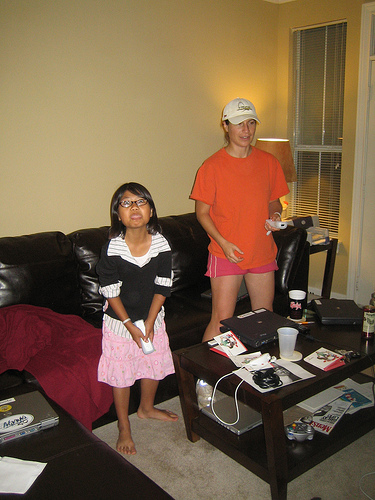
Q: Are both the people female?
A: Yes, all the people are female.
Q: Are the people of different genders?
A: No, all the people are female.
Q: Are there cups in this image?
A: Yes, there is a cup.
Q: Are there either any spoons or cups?
A: Yes, there is a cup.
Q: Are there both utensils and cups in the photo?
A: No, there is a cup but no utensils.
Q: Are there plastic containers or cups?
A: Yes, there is a plastic cup.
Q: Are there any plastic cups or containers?
A: Yes, there is a plastic cup.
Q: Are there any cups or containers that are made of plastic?
A: Yes, the cup is made of plastic.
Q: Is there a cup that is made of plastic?
A: Yes, there is a cup that is made of plastic.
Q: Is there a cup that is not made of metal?
A: Yes, there is a cup that is made of plastic.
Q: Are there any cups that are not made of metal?
A: Yes, there is a cup that is made of plastic.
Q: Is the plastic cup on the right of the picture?
A: Yes, the cup is on the right of the image.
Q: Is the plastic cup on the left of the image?
A: No, the cup is on the right of the image.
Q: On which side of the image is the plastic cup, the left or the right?
A: The cup is on the right of the image.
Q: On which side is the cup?
A: The cup is on the right of the image.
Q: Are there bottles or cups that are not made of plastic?
A: No, there is a cup but it is made of plastic.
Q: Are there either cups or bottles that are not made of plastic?
A: No, there is a cup but it is made of plastic.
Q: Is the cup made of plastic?
A: Yes, the cup is made of plastic.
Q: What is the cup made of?
A: The cup is made of plastic.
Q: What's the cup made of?
A: The cup is made of plastic.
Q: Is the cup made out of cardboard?
A: No, the cup is made of plastic.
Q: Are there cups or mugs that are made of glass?
A: No, there is a cup but it is made of plastic.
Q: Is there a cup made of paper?
A: No, there is a cup but it is made of plastic.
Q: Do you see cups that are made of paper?
A: No, there is a cup but it is made of plastic.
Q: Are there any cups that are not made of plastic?
A: No, there is a cup but it is made of plastic.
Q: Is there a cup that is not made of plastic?
A: No, there is a cup but it is made of plastic.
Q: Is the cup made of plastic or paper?
A: The cup is made of plastic.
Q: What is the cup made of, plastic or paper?
A: The cup is made of plastic.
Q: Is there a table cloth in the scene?
A: No, there are no tablecloths.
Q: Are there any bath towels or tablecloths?
A: No, there are no tablecloths or bath towels.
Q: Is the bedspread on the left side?
A: Yes, the bedspread is on the left of the image.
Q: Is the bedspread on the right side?
A: No, the bedspread is on the left of the image.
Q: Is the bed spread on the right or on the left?
A: The bed spread is on the left of the image.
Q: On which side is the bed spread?
A: The bed spread is on the left of the image.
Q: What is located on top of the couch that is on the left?
A: The bedspread is on top of the couch.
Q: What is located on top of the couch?
A: The bedspread is on top of the couch.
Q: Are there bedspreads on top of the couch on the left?
A: Yes, there is a bedspread on top of the couch.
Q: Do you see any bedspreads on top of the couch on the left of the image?
A: Yes, there is a bedspread on top of the couch.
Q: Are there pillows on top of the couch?
A: No, there is a bedspread on top of the couch.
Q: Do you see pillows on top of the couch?
A: No, there is a bedspread on top of the couch.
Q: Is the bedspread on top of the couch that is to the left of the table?
A: Yes, the bedspread is on top of the couch.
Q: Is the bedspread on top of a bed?
A: No, the bedspread is on top of the couch.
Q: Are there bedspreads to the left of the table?
A: Yes, there is a bedspread to the left of the table.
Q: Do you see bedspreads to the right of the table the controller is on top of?
A: No, the bedspread is to the left of the table.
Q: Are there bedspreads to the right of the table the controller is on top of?
A: No, the bedspread is to the left of the table.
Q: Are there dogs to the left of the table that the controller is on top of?
A: No, there is a bedspread to the left of the table.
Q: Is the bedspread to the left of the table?
A: Yes, the bedspread is to the left of the table.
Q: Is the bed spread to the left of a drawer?
A: No, the bed spread is to the left of the table.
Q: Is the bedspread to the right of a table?
A: No, the bedspread is to the left of a table.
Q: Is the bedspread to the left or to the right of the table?
A: The bedspread is to the left of the table.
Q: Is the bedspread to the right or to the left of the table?
A: The bedspread is to the left of the table.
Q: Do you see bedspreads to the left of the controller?
A: Yes, there is a bedspread to the left of the controller.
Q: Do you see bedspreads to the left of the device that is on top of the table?
A: Yes, there is a bedspread to the left of the controller.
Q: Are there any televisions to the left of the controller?
A: No, there is a bedspread to the left of the controller.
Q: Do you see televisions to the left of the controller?
A: No, there is a bedspread to the left of the controller.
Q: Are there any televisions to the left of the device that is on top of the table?
A: No, there is a bedspread to the left of the controller.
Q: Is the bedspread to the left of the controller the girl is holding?
A: Yes, the bedspread is to the left of the controller.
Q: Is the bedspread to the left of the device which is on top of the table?
A: Yes, the bedspread is to the left of the controller.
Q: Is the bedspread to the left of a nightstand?
A: No, the bedspread is to the left of the controller.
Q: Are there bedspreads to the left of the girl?
A: Yes, there is a bedspread to the left of the girl.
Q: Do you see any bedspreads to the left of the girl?
A: Yes, there is a bedspread to the left of the girl.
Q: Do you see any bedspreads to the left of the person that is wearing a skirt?
A: Yes, there is a bedspread to the left of the girl.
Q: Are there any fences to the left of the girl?
A: No, there is a bedspread to the left of the girl.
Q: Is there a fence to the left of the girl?
A: No, there is a bedspread to the left of the girl.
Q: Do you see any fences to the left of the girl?
A: No, there is a bedspread to the left of the girl.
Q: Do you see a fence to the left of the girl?
A: No, there is a bedspread to the left of the girl.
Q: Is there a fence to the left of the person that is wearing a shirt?
A: No, there is a bedspread to the left of the girl.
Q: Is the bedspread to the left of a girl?
A: Yes, the bedspread is to the left of a girl.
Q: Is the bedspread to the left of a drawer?
A: No, the bedspread is to the left of a girl.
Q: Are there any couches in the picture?
A: Yes, there is a couch.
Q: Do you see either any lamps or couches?
A: Yes, there is a couch.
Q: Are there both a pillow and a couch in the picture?
A: No, there is a couch but no pillows.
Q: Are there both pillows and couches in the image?
A: No, there is a couch but no pillows.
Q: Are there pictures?
A: No, there are no pictures.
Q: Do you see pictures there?
A: No, there are no pictures.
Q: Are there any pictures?
A: No, there are no pictures.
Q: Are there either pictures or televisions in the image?
A: No, there are no pictures or televisions.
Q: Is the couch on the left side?
A: Yes, the couch is on the left of the image.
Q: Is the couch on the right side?
A: No, the couch is on the left of the image.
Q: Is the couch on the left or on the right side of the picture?
A: The couch is on the left of the image.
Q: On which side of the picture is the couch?
A: The couch is on the left of the image.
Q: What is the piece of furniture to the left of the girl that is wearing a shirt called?
A: The piece of furniture is a couch.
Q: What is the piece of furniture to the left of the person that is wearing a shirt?
A: The piece of furniture is a couch.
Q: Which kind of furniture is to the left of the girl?
A: The piece of furniture is a couch.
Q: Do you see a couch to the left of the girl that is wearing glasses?
A: Yes, there is a couch to the left of the girl.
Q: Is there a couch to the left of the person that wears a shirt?
A: Yes, there is a couch to the left of the girl.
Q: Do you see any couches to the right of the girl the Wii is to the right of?
A: No, the couch is to the left of the girl.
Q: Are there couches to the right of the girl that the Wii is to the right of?
A: No, the couch is to the left of the girl.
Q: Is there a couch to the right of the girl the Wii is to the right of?
A: No, the couch is to the left of the girl.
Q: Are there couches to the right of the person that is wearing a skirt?
A: No, the couch is to the left of the girl.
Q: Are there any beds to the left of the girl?
A: No, there is a couch to the left of the girl.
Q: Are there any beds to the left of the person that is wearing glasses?
A: No, there is a couch to the left of the girl.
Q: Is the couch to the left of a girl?
A: Yes, the couch is to the left of a girl.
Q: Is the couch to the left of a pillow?
A: No, the couch is to the left of a girl.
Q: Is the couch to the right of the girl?
A: No, the couch is to the left of the girl.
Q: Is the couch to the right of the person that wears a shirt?
A: No, the couch is to the left of the girl.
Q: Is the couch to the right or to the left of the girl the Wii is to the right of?
A: The couch is to the left of the girl.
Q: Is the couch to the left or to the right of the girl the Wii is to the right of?
A: The couch is to the left of the girl.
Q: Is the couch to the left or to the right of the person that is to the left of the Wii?
A: The couch is to the left of the girl.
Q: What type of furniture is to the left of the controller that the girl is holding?
A: The piece of furniture is a couch.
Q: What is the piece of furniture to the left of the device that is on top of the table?
A: The piece of furniture is a couch.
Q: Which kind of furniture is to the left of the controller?
A: The piece of furniture is a couch.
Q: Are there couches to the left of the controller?
A: Yes, there is a couch to the left of the controller.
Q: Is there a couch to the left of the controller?
A: Yes, there is a couch to the left of the controller.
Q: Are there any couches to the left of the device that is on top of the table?
A: Yes, there is a couch to the left of the controller.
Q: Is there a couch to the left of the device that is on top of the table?
A: Yes, there is a couch to the left of the controller.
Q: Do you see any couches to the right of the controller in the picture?
A: No, the couch is to the left of the controller.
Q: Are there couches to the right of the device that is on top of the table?
A: No, the couch is to the left of the controller.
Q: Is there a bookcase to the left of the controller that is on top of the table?
A: No, there is a couch to the left of the controller.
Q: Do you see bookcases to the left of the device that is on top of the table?
A: No, there is a couch to the left of the controller.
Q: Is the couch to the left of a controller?
A: Yes, the couch is to the left of a controller.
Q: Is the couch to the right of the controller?
A: No, the couch is to the left of the controller.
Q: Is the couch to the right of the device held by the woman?
A: No, the couch is to the left of the controller.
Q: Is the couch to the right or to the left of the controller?
A: The couch is to the left of the controller.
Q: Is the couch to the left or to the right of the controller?
A: The couch is to the left of the controller.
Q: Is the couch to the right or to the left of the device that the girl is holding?
A: The couch is to the left of the controller.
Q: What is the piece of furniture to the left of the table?
A: The piece of furniture is a couch.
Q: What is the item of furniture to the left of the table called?
A: The piece of furniture is a couch.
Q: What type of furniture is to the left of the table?
A: The piece of furniture is a couch.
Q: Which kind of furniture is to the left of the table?
A: The piece of furniture is a couch.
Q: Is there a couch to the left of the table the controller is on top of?
A: Yes, there is a couch to the left of the table.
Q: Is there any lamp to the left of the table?
A: No, there is a couch to the left of the table.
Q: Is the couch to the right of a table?
A: No, the couch is to the left of a table.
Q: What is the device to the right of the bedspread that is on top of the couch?
A: The device is a controller.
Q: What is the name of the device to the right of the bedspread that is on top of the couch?
A: The device is a controller.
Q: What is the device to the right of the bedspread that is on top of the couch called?
A: The device is a controller.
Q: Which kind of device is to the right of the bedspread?
A: The device is a controller.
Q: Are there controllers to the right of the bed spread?
A: Yes, there is a controller to the right of the bed spread.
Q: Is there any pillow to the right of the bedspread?
A: No, there is a controller to the right of the bedspread.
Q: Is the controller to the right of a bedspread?
A: Yes, the controller is to the right of a bedspread.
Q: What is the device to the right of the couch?
A: The device is a controller.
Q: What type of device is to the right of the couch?
A: The device is a controller.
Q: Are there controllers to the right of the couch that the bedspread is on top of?
A: Yes, there is a controller to the right of the couch.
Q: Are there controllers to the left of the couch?
A: No, the controller is to the right of the couch.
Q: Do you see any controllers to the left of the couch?
A: No, the controller is to the right of the couch.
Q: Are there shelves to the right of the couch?
A: No, there is a controller to the right of the couch.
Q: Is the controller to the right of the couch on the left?
A: Yes, the controller is to the right of the couch.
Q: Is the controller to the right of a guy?
A: No, the controller is to the right of the couch.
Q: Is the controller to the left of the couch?
A: No, the controller is to the right of the couch.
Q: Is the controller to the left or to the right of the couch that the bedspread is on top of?
A: The controller is to the right of the couch.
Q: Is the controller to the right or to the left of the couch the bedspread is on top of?
A: The controller is to the right of the couch.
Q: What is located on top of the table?
A: The controller is on top of the table.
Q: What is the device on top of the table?
A: The device is a controller.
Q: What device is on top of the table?
A: The device is a controller.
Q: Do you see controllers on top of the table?
A: Yes, there is a controller on top of the table.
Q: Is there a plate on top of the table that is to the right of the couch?
A: No, there is a controller on top of the table.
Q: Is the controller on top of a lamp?
A: No, the controller is on top of the table.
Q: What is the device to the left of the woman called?
A: The device is a controller.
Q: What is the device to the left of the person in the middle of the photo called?
A: The device is a controller.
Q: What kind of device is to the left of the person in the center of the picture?
A: The device is a controller.